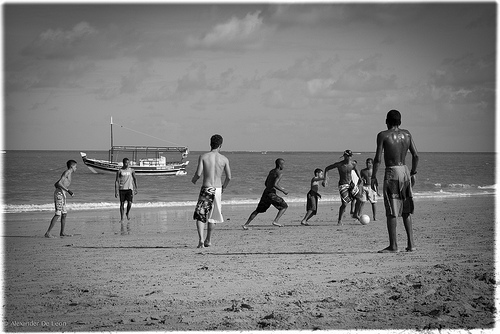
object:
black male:
[370, 109, 421, 253]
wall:
[394, 120, 406, 172]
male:
[191, 134, 233, 248]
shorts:
[255, 188, 288, 214]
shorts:
[306, 189, 318, 214]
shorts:
[119, 188, 133, 203]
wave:
[7, 180, 497, 215]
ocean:
[3, 149, 498, 213]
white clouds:
[203, 10, 263, 46]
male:
[241, 157, 289, 229]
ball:
[358, 214, 371, 225]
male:
[321, 148, 363, 225]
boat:
[79, 112, 189, 177]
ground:
[319, 58, 368, 93]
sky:
[4, 2, 497, 154]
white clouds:
[304, 74, 335, 95]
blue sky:
[4, 3, 497, 152]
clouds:
[2, 3, 495, 152]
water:
[4, 152, 496, 210]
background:
[0, 3, 499, 195]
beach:
[2, 201, 494, 331]